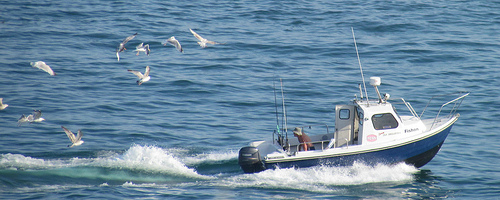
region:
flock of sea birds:
[5, 23, 217, 152]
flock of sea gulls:
[5, 20, 217, 158]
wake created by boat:
[101, 138, 246, 190]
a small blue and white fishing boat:
[242, 15, 468, 196]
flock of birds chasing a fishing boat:
[1, 26, 471, 193]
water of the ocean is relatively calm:
[242, 13, 341, 80]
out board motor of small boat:
[238, 138, 276, 179]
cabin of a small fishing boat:
[351, 98, 399, 145]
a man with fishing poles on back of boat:
[266, 62, 316, 157]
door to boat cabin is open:
[332, 98, 372, 148]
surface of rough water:
[4, 2, 497, 195]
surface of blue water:
[4, 4, 497, 194]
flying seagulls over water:
[0, 29, 214, 150]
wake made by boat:
[0, 144, 241, 183]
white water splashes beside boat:
[256, 158, 417, 189]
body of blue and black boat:
[263, 115, 456, 171]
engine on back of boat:
[237, 145, 260, 172]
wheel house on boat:
[354, 98, 416, 140]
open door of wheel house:
[331, 105, 366, 147]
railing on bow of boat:
[426, 91, 470, 127]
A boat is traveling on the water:
[2, 12, 490, 193]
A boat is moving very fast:
[15, 11, 485, 197]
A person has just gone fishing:
[15, 8, 495, 188]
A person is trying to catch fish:
[15, 15, 491, 195]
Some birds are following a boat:
[12, 5, 497, 190]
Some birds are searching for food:
[15, 10, 496, 188]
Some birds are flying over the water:
[12, 6, 224, 186]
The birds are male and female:
[12, 17, 223, 180]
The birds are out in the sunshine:
[10, 11, 223, 196]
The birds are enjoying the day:
[17, 18, 220, 179]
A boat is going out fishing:
[7, 10, 490, 195]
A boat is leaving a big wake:
[3, 10, 489, 196]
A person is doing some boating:
[6, 8, 481, 194]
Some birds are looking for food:
[10, 11, 225, 196]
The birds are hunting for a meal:
[11, 13, 224, 185]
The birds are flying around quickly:
[17, 11, 213, 197]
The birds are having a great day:
[12, 9, 229, 189]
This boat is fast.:
[247, 28, 462, 183]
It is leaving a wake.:
[15, 36, 472, 190]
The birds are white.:
[15, 17, 224, 143]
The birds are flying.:
[15, 13, 223, 140]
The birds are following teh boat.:
[0, 29, 225, 144]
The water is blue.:
[229, 18, 344, 67]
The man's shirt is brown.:
[292, 128, 312, 153]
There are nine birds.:
[0, 21, 224, 150]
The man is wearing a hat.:
[293, 128, 313, 154]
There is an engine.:
[237, 146, 263, 174]